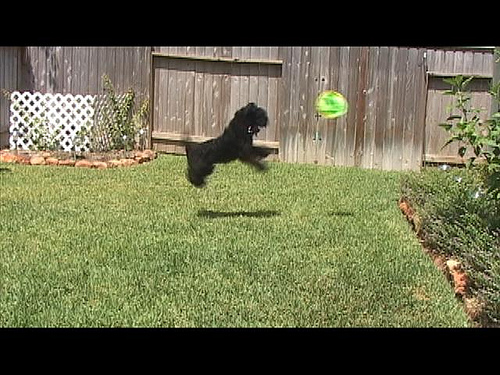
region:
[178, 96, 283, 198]
A black dog jumping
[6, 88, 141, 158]
A white fence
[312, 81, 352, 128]
A yellow and green ball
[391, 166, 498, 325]
Green landscaped bushes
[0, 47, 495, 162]
A tall wooden fence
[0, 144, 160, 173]
A border of stones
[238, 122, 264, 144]
A tag on the dog's collar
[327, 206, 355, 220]
The shadow of the ball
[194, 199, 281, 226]
The jumping dog's shadow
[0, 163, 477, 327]
Freshly mowed green grass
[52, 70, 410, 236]
dog is playing in yard with toy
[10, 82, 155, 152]
small white lattice fence in corner of yard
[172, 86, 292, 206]
totally black dog jumping on grass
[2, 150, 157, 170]
curved row of stones by plantings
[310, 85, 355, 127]
round green toy in the air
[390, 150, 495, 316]
row of planting by side of yard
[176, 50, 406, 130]
wooden fence made from slats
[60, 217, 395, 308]
green thick lawn of grass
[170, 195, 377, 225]
shadow of dog and toy as long and short lines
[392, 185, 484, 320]
border of stones hidden by plant growth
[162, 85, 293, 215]
the dog is black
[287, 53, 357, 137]
the ball is green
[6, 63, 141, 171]
the garden fence is white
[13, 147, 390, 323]
the grass is green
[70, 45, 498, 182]
the fence is wooden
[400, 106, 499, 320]
the bushes are green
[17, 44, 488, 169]
the fence is brown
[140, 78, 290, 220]
the dog is jumping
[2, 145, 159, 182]
brown stones are in front of the white fence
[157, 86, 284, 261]
the dog's shadow is on the ground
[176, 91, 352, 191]
Black dog jumping to catch a toy.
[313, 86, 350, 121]
Green toy in the air.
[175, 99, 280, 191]
Black dog.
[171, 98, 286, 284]
Black dog jumping off the grass.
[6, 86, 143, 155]
White trellis.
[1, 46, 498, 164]
Brown wooden fence.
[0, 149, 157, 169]
Rocks.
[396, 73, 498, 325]
Garden area with low bushes.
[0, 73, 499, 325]
Lawn with some areas set apart for landscaping.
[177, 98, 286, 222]
Black dog and its shadow on the grass.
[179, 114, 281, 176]
The dog is black.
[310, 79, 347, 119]
The ball is green and yellow.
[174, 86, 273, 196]
The dog is by the fence.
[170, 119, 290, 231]
The dog is playing in the grass.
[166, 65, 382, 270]
the dog is playing in the yard.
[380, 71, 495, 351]
There are shrubs in the yard.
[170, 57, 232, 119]
The fence is made of wood.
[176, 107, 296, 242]
The dog is jumping.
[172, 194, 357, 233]
The dog's shadow is appearing on the grass.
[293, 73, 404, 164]
The ball is in the air.